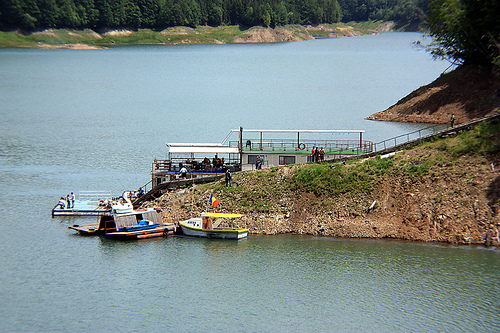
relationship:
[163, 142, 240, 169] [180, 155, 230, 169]
structure full of people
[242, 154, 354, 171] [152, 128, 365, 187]
wall of a building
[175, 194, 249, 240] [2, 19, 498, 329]
boat on water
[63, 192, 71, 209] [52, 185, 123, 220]
person on a floating floating dock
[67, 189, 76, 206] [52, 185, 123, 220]
person on a floating floating dock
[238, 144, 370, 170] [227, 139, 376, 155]
building with rail